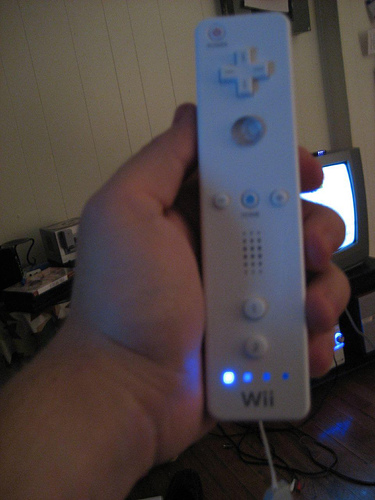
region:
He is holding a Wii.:
[234, 384, 289, 411]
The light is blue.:
[201, 362, 243, 394]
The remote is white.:
[174, 17, 316, 433]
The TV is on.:
[305, 147, 373, 246]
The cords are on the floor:
[232, 417, 372, 488]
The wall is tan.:
[27, 24, 113, 116]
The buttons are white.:
[189, 16, 322, 419]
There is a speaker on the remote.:
[230, 225, 271, 281]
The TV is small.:
[285, 149, 366, 275]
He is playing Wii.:
[2, 0, 345, 473]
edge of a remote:
[230, 408, 259, 425]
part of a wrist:
[117, 373, 160, 415]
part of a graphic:
[238, 385, 265, 409]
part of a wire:
[257, 447, 281, 467]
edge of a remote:
[217, 410, 257, 433]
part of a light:
[213, 364, 247, 387]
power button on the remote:
[189, 17, 238, 50]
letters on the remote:
[230, 383, 283, 417]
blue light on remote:
[203, 358, 248, 399]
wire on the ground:
[302, 434, 343, 470]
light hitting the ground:
[325, 394, 361, 448]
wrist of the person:
[55, 315, 179, 459]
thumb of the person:
[155, 103, 208, 178]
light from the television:
[319, 150, 361, 209]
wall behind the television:
[73, 51, 126, 92]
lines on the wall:
[5, 32, 162, 114]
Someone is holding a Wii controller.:
[166, 166, 374, 434]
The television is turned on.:
[300, 135, 370, 315]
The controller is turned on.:
[218, 353, 298, 399]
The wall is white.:
[62, 34, 167, 100]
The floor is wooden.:
[328, 406, 368, 445]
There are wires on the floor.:
[243, 435, 353, 477]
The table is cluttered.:
[10, 230, 62, 320]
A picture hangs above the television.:
[214, 2, 315, 16]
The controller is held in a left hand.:
[77, 188, 169, 405]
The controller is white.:
[218, 159, 295, 293]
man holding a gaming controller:
[79, 11, 364, 442]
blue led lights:
[214, 364, 304, 394]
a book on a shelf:
[15, 265, 68, 300]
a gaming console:
[325, 320, 351, 371]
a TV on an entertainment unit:
[306, 142, 371, 271]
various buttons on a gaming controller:
[211, 48, 294, 325]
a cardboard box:
[36, 218, 82, 263]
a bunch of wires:
[223, 428, 358, 481]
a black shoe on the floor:
[159, 466, 205, 496]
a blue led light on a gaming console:
[332, 326, 353, 353]